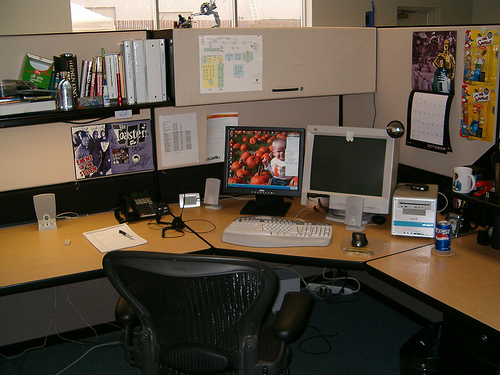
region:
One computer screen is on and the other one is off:
[217, 118, 398, 217]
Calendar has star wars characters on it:
[398, 28, 461, 169]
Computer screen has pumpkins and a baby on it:
[218, 123, 305, 200]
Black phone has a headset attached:
[100, 191, 190, 241]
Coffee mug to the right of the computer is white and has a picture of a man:
[445, 162, 475, 197]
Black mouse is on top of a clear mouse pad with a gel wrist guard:
[340, 230, 380, 263]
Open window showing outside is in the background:
[60, 7, 344, 37]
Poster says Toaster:
[62, 119, 169, 181]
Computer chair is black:
[98, 248, 333, 365]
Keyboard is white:
[223, 209, 336, 259]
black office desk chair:
[93, 244, 312, 374]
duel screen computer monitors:
[221, 118, 401, 211]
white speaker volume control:
[26, 186, 64, 232]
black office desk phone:
[115, 188, 170, 222]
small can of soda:
[435, 217, 452, 252]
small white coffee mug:
[447, 160, 480, 195]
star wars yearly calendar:
[404, 25, 454, 155]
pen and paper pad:
[82, 223, 159, 252]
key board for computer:
[218, 207, 335, 253]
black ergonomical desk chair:
[99, 240, 314, 374]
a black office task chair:
[96, 250, 316, 372]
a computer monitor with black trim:
[222, 126, 302, 193]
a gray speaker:
[30, 191, 55, 226]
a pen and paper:
[82, 222, 142, 247]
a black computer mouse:
[350, 229, 368, 249]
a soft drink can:
[435, 219, 453, 251]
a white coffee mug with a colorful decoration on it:
[450, 165, 474, 194]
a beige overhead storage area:
[0, 26, 383, 123]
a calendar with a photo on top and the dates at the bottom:
[407, 31, 452, 152]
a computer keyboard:
[219, 215, 333, 248]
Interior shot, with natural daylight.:
[5, 4, 497, 372]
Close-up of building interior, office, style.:
[3, 5, 499, 374]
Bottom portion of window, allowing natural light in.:
[69, 1, 326, 33]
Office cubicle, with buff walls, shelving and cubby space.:
[0, 24, 490, 256]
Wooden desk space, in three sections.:
[7, 200, 499, 332]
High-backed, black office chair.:
[106, 248, 341, 363]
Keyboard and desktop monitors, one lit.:
[222, 124, 390, 250]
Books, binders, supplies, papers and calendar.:
[16, 48, 496, 161]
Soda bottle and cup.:
[431, 161, 472, 266]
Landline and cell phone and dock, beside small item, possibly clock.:
[103, 178, 227, 238]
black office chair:
[97, 244, 289, 371]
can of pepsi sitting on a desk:
[431, 217, 456, 255]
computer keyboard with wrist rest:
[218, 213, 335, 251]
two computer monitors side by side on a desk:
[220, 117, 396, 223]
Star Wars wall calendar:
[401, 27, 459, 155]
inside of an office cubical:
[2, 21, 497, 371]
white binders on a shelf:
[120, 34, 172, 109]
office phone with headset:
[107, 193, 192, 241]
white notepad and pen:
[82, 220, 150, 254]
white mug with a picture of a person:
[447, 162, 478, 198]